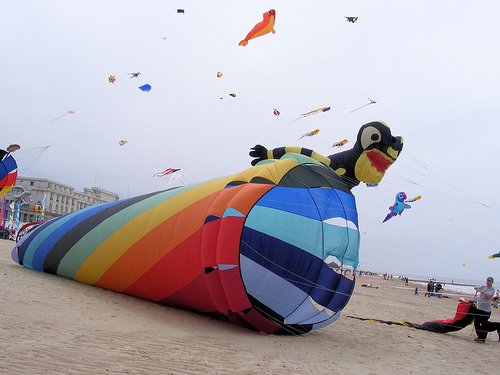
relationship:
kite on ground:
[11, 121, 403, 338] [1, 235, 497, 368]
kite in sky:
[301, 127, 318, 135] [1, 1, 498, 281]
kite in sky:
[104, 70, 117, 85] [358, 24, 499, 127]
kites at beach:
[92, 69, 156, 104] [2, 225, 492, 375]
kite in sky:
[238, 9, 277, 46] [5, 57, 486, 264]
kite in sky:
[98, 64, 124, 84] [364, 30, 458, 114]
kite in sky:
[296, 105, 329, 122] [1, 1, 498, 281]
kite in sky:
[136, 79, 155, 96] [6, 12, 471, 279]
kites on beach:
[53, 3, 386, 118] [74, 279, 468, 372]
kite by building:
[100, 138, 135, 158] [22, 179, 107, 220]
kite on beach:
[11, 121, 403, 338] [1, 312, 484, 372]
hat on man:
[479, 278, 498, 286] [465, 272, 485, 352]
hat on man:
[486, 277, 494, 286] [482, 285, 484, 338]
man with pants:
[465, 268, 499, 341] [463, 303, 493, 338]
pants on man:
[463, 303, 493, 338] [465, 268, 499, 341]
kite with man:
[221, 11, 285, 56] [476, 274, 485, 338]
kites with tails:
[296, 103, 333, 118] [245, 24, 265, 57]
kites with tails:
[351, 97, 378, 111] [378, 195, 396, 233]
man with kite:
[473, 276, 499, 344] [383, 272, 476, 352]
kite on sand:
[341, 296, 476, 328] [0, 239, 496, 371]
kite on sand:
[10, 152, 356, 339] [0, 239, 496, 371]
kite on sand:
[238, 9, 277, 46] [0, 239, 496, 371]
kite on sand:
[381, 188, 418, 223] [0, 239, 496, 371]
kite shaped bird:
[383, 189, 414, 221] [382, 189, 406, 226]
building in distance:
[225, 6, 309, 60] [3, 157, 160, 249]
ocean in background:
[383, 275, 498, 292] [356, 258, 498, 291]